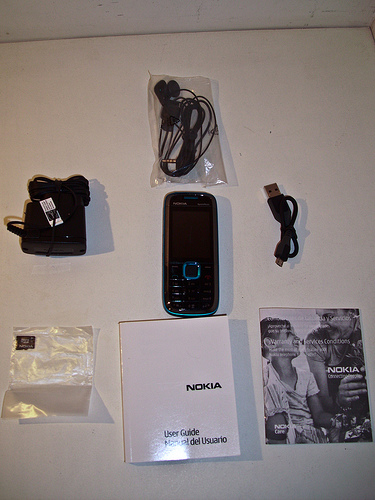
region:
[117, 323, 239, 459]
A user guide for the phone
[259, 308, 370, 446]
A warranty book for the phone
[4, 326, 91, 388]
A clear plastic bag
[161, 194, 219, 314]
A cell phone on the table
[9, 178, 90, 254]
A charger for the phone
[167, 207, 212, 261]
The screen for the phone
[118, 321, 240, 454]
A user guide for a Nokia phoe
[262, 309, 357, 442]
Two people on the cover of the warranty guide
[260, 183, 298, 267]
A connector device for the phone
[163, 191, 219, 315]
The phone is in the shape of a rectangle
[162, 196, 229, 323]
a mobile phone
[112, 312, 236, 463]
a white phone manual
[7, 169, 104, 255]
a charger of a mobile phone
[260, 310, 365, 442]
people talking on themanuals cover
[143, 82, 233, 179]
a phones earphones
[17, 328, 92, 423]
an empty polythene sheets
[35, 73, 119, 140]
a white shiny surface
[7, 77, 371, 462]
components of a mobile phone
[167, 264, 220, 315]
the phones keypad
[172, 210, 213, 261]
the phones screen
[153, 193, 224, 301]
this is a phone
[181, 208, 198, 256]
the phone is black in color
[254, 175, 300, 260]
this is a usb cable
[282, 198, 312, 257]
the cable is black in color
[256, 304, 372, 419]
this is a booklet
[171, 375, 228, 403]
this is a writing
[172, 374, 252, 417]
the writing is in black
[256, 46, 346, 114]
this is the wall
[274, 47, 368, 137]
the wall is white in color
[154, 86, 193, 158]
this is the ear phone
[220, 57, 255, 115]
part of a durface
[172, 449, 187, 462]
edge fo a box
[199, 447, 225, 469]
edge of a box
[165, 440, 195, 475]
edge fo a box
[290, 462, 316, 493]
part of a surface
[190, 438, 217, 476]
edge of a box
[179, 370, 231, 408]
word on the book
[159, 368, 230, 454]
many words on the book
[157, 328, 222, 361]
white front of the book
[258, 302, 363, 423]
picture on the front of the book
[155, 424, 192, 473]
light hitting the book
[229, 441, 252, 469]
corner of the book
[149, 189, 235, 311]
phone on the table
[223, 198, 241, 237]
shadow under the phone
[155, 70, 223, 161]
headphones in a bag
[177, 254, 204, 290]
middle button on the phone